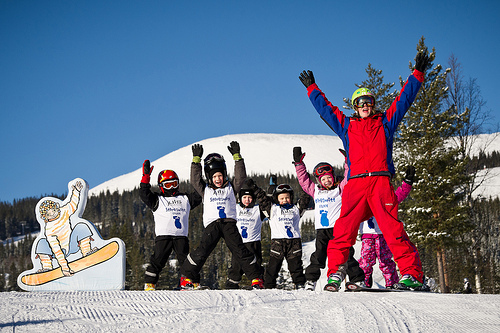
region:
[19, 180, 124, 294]
a skater figure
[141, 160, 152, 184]
the glove is red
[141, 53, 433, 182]
they have their hands up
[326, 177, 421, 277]
this is a red pant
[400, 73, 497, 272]
a tree behind the skater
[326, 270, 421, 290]
he is wearing a green boots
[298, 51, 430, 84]
a couple of black gloves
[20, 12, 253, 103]
a neat blue sky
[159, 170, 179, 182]
the skater helmet is red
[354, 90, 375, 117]
the head of the skater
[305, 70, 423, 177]
a red and blue winter coat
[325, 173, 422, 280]
a pair of red snow pants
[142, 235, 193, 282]
a pair of child's black snow pants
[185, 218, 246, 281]
a pair of child's black snow pants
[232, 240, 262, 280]
a pair of child's black snow pants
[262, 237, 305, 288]
a pair of child's black snow pants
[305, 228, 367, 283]
a pair of child's black snow pants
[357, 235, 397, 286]
a pair of child's pink snow pants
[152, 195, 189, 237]
a white participation vest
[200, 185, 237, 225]
a white participation vest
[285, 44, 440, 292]
snowboarder on the top of a slope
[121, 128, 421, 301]
children snowboarders in a class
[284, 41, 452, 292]
snowboard teacher has his hands in the air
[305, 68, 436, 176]
person is wearing a red and blue jacket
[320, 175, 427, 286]
red snowboarder pants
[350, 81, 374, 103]
yellow helmet on the snowboarder's head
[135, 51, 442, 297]
a snowboarding lesson is happening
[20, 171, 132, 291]
sign with a snowboarder picture on it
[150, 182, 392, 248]
the kids are all wearing the same shirt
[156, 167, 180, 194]
kid has helmet and snow glasses on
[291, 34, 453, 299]
skier wearing red and blue skisuit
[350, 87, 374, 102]
lime green helmet skier is wearing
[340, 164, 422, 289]
child wearing all pink skisuit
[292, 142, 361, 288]
child wearing pink coat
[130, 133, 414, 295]
children wearing white sleeveless shirts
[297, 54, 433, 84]
black gloves adult skier is wearing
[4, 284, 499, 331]
tracks in the snow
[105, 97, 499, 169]
mountain behind the skier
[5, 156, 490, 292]
trees on the mountainside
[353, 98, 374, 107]
snow goggles adult is wearing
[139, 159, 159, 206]
the arm up of a small child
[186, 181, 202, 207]
the arm up of a small child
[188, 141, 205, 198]
the arm up of a small child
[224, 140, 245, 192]
the arm up of a small childthe arm up of a small child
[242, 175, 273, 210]
the arm up of a small child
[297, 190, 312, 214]
the arm up of a small child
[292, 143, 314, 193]
the arm up of a small child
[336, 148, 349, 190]
the arm up of a small child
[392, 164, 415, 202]
the arm up of a small child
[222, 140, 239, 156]
the black glove